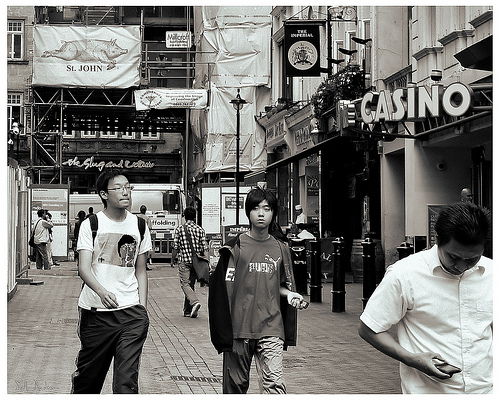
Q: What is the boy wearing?
A: Shirt.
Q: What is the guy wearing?
A: Pants.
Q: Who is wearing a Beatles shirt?
A: The guy on the left.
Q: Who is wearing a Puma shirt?
A: The guy walking down the street.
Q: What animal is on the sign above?
A: A pig.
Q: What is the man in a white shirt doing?
A: Checking his phone.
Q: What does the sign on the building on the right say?
A: CASINO.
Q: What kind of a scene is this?
A: A city street.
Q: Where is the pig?
A: On the sign.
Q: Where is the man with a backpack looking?
A: To the right.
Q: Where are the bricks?
A: On the street.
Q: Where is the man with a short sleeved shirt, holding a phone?
A: In the bottom right corner.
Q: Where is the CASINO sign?
A: On the right side above the people walking.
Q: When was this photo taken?
A: During the daytime.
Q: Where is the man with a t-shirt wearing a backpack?
A: On the left side.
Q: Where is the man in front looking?
A: At the phone in his hand.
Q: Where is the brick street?
A: Under the people walking.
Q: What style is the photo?
A: Black and white.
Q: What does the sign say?
A: Casino.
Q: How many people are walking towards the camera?
A: Three.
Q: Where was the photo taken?
A: Street.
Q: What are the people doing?
A: Walking.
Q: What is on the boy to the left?
A: Backpack.